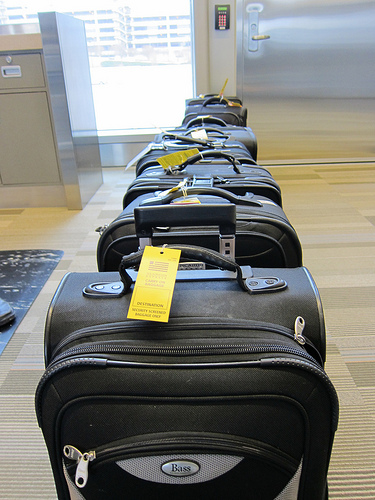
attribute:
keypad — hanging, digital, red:
[213, 1, 232, 35]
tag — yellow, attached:
[123, 243, 181, 328]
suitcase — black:
[48, 254, 339, 499]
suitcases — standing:
[30, 90, 341, 498]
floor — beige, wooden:
[0, 136, 373, 500]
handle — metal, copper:
[246, 27, 272, 48]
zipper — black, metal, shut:
[52, 324, 323, 371]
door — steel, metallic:
[236, 5, 374, 140]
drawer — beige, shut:
[2, 34, 65, 208]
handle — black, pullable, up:
[133, 206, 236, 262]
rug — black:
[3, 246, 62, 355]